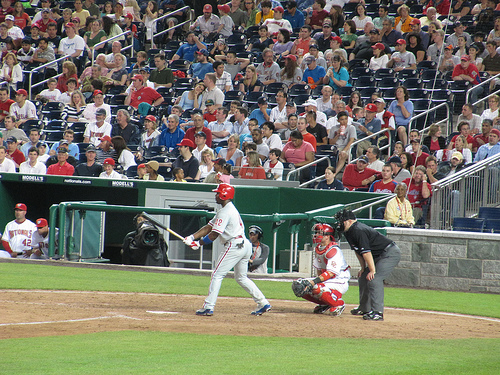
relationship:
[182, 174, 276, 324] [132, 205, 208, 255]
batter holding bat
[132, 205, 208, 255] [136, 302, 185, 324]
bat over plate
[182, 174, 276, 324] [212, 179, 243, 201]
batter wearing helmet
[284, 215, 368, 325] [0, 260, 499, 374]
catcher on ground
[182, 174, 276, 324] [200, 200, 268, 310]
batter wearing uniform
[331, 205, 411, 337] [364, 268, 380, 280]
umpire has hand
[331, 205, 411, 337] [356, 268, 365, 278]
umpire has hand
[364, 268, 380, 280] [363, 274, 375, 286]
hand on knee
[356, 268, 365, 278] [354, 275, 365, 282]
hand on knee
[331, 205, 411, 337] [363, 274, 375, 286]
umpire has knee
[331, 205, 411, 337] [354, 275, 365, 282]
umpire has knee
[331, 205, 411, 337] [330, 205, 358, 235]
umpire wearing helmet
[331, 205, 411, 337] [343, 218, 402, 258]
umpire wearing shirt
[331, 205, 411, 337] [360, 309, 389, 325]
umpire wearing shoe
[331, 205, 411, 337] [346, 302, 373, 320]
umpire wearing shoe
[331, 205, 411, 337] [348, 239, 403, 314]
umpire wearing pants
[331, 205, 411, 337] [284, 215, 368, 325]
umpire behind catcher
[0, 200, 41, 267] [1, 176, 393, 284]
player in dugout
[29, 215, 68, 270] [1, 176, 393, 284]
player in dugout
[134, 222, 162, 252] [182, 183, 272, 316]
camera pointed at batter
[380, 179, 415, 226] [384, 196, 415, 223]
man wears shirt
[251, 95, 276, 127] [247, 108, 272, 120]
man wears shirt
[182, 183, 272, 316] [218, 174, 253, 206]
batter wears hat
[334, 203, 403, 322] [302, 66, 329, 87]
man wears blue shirt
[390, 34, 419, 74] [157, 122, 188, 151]
man wears blue shirt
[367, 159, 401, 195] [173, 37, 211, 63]
man wears blue shirt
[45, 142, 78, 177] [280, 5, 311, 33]
man wears blue shirt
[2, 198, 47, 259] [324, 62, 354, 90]
man wears blue shirt